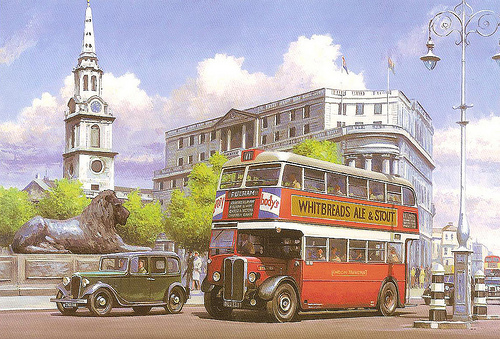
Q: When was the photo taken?
A: Daytime.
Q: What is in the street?
A: A bus.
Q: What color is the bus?
A: Red and white.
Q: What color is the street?
A: Red.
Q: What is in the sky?
A: Clouds.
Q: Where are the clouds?
A: In the sky.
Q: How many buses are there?
A: One.